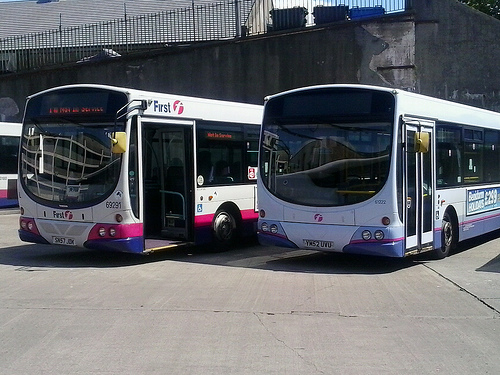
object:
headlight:
[374, 230, 384, 241]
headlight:
[109, 229, 116, 237]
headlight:
[20, 220, 26, 228]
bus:
[17, 83, 266, 256]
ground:
[0, 206, 500, 375]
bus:
[256, 83, 500, 259]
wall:
[403, 0, 497, 112]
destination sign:
[49, 107, 103, 115]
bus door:
[143, 122, 197, 251]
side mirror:
[414, 131, 429, 152]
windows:
[20, 122, 123, 201]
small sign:
[436, 211, 439, 219]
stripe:
[121, 208, 262, 239]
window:
[433, 124, 460, 188]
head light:
[27, 221, 33, 230]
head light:
[98, 227, 107, 237]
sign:
[465, 187, 500, 217]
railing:
[0, 0, 404, 50]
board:
[39, 92, 109, 117]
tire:
[209, 209, 242, 249]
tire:
[432, 211, 454, 258]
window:
[262, 123, 391, 206]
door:
[401, 123, 437, 252]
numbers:
[106, 201, 122, 209]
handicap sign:
[197, 204, 202, 212]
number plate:
[53, 236, 76, 245]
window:
[198, 129, 247, 184]